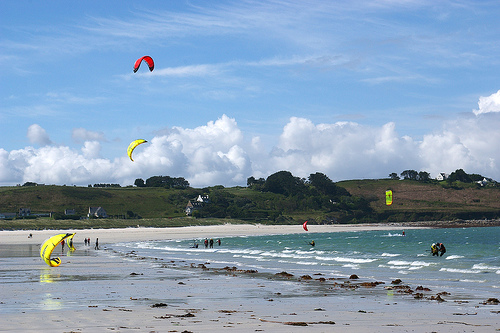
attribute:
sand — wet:
[0, 239, 497, 331]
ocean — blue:
[152, 221, 497, 301]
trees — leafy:
[126, 160, 212, 199]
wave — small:
[328, 224, 408, 277]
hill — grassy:
[2, 169, 499, 228]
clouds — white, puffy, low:
[7, 87, 495, 194]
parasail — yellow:
[37, 230, 78, 275]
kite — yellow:
[116, 41, 169, 86]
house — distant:
[191, 192, 203, 206]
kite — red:
[298, 219, 315, 237]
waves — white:
[136, 245, 491, 287]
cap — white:
[445, 249, 466, 261]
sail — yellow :
[383, 185, 394, 210]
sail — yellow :
[37, 230, 77, 274]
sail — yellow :
[129, 51, 159, 78]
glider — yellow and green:
[384, 187, 393, 207]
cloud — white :
[471, 90, 498, 116]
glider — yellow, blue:
[28, 226, 79, 271]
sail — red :
[300, 217, 311, 234]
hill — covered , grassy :
[213, 179, 488, 220]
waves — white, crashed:
[147, 239, 499, 275]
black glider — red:
[45, 54, 175, 194]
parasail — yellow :
[38, 230, 74, 270]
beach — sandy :
[0, 222, 499, 330]